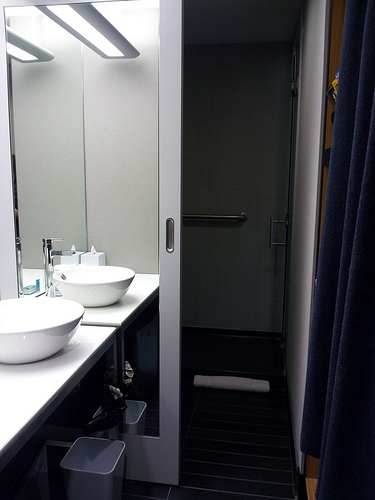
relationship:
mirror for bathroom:
[124, 172, 241, 396] [60, 219, 128, 420]